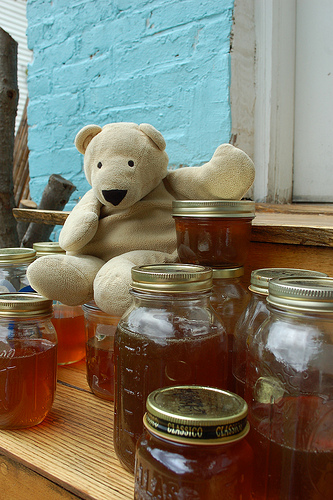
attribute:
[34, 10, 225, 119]
brick building — blue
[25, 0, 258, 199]
brick wall — blue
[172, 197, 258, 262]
jar — short, clear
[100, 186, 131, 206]
nose — bear's, triangular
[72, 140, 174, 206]
face — light brown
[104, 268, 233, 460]
jar — golden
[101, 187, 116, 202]
nose — black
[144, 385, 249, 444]
lid — gold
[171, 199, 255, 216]
lid — gold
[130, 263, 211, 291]
lid — gold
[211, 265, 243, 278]
lid — gold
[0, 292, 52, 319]
lid — gold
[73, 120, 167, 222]
bear — sitting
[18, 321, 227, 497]
table — brown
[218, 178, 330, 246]
step — wooden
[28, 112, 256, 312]
bear — tan, teddy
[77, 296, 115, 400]
jar — small, glass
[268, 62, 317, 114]
door — white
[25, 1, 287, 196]
wall — light green, bricked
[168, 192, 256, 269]
jar — glass, small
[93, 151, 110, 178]
eye — black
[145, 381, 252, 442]
lid — jar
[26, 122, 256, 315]
teddy bear — brown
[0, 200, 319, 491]
jars — honey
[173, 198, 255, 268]
jar — smaller, honey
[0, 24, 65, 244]
tree — dark brown, trimmed